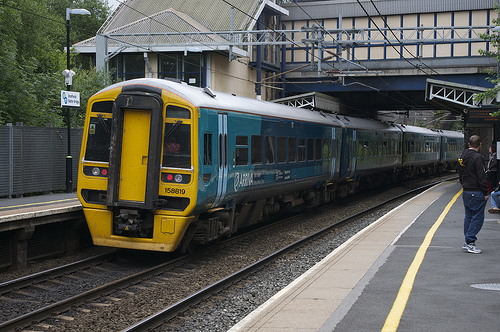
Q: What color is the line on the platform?
A: Yellow.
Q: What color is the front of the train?
A: Yellow.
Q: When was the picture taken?
A: Daytime.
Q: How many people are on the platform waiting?
A: Two.